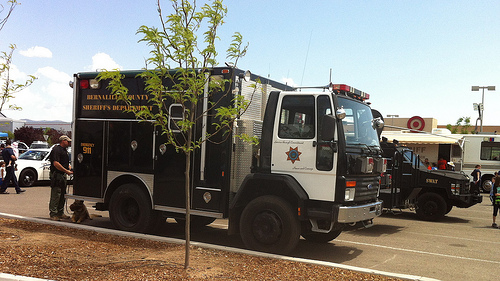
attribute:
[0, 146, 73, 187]
police car — white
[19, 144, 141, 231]
man — working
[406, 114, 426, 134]
bull eyes — red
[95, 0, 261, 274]
tree — very young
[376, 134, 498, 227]
police presence — military, extra, backup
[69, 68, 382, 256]
truck — major, police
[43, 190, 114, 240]
dog — police, awaiting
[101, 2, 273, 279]
tree — young 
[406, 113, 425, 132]
sign — orange 